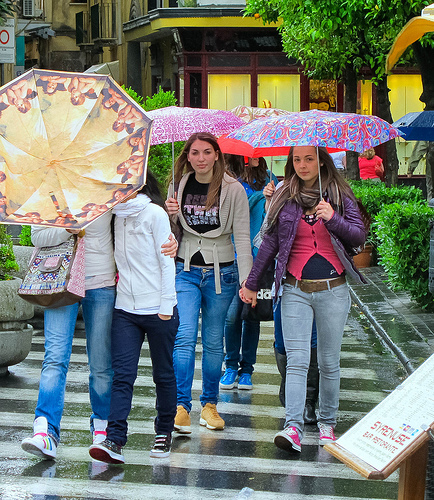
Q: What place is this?
A: It is a sidewalk.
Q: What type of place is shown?
A: It is a sidewalk.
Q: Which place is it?
A: It is a sidewalk.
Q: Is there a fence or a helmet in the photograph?
A: No, there are no fences or helmets.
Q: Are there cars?
A: No, there are no cars.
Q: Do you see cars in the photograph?
A: No, there are no cars.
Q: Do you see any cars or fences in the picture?
A: No, there are no cars or fences.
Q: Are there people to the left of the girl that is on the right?
A: Yes, there is a person to the left of the girl.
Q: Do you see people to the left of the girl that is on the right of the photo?
A: Yes, there is a person to the left of the girl.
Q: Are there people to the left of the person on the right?
A: Yes, there is a person to the left of the girl.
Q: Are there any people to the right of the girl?
A: No, the person is to the left of the girl.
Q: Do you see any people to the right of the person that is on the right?
A: No, the person is to the left of the girl.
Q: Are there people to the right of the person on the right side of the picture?
A: No, the person is to the left of the girl.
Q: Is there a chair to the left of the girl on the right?
A: No, there is a person to the left of the girl.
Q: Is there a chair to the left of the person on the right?
A: No, there is a person to the left of the girl.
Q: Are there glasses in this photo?
A: No, there are no glasses.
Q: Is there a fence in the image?
A: No, there are no fences.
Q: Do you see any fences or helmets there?
A: No, there are no fences or helmets.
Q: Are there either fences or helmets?
A: No, there are no fences or helmets.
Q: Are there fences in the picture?
A: No, there are no fences.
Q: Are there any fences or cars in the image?
A: No, there are no fences or cars.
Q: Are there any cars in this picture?
A: No, there are no cars.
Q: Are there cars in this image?
A: No, there are no cars.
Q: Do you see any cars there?
A: No, there are no cars.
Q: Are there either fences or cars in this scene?
A: No, there are no cars or fences.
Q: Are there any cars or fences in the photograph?
A: No, there are no cars or fences.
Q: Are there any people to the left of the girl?
A: Yes, there is a person to the left of the girl.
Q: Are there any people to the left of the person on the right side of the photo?
A: Yes, there is a person to the left of the girl.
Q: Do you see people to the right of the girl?
A: No, the person is to the left of the girl.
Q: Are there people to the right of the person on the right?
A: No, the person is to the left of the girl.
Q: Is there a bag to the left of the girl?
A: No, there is a person to the left of the girl.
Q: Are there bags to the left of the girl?
A: No, there is a person to the left of the girl.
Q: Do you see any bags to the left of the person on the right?
A: No, there is a person to the left of the girl.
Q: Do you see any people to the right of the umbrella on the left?
A: Yes, there is a person to the right of the umbrella.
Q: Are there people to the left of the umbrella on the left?
A: No, the person is to the right of the umbrella.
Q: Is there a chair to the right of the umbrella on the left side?
A: No, there is a person to the right of the umbrella.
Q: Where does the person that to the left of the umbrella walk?
A: The person walks on the sidewalk.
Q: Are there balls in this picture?
A: No, there are no balls.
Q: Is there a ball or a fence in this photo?
A: No, there are no balls or fences.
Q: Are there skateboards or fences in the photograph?
A: No, there are no fences or skateboards.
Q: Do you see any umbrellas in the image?
A: Yes, there is an umbrella.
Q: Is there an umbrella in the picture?
A: Yes, there is an umbrella.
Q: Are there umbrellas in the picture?
A: Yes, there is an umbrella.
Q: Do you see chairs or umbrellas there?
A: Yes, there is an umbrella.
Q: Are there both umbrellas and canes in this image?
A: No, there is an umbrella but no canes.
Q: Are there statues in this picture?
A: No, there are no statues.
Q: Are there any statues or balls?
A: No, there are no statues or balls.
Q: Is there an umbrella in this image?
A: Yes, there is an umbrella.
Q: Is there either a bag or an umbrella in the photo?
A: Yes, there is an umbrella.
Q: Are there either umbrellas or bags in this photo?
A: Yes, there is an umbrella.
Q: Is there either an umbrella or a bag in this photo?
A: Yes, there is an umbrella.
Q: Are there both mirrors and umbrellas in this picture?
A: No, there is an umbrella but no mirrors.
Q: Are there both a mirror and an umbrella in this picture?
A: No, there is an umbrella but no mirrors.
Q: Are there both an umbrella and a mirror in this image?
A: No, there is an umbrella but no mirrors.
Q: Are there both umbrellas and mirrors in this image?
A: No, there is an umbrella but no mirrors.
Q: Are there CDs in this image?
A: No, there are no cds.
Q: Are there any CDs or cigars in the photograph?
A: No, there are no CDs or cigars.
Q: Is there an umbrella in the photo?
A: Yes, there is an umbrella.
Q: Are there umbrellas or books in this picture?
A: Yes, there is an umbrella.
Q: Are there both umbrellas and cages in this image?
A: No, there is an umbrella but no cages.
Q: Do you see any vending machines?
A: No, there are no vending machines.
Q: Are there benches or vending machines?
A: No, there are no vending machines or benches.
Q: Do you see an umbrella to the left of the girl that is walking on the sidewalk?
A: Yes, there is an umbrella to the left of the girl.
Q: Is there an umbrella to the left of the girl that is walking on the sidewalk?
A: Yes, there is an umbrella to the left of the girl.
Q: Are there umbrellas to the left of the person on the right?
A: Yes, there is an umbrella to the left of the girl.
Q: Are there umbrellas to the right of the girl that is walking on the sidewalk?
A: No, the umbrella is to the left of the girl.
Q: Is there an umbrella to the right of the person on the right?
A: No, the umbrella is to the left of the girl.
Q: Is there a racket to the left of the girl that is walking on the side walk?
A: No, there is an umbrella to the left of the girl.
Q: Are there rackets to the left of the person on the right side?
A: No, there is an umbrella to the left of the girl.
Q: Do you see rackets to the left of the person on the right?
A: No, there is an umbrella to the left of the girl.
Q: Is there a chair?
A: No, there are no chairs.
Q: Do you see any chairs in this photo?
A: No, there are no chairs.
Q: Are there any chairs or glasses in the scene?
A: No, there are no chairs or glasses.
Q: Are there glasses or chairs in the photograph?
A: No, there are no chairs or glasses.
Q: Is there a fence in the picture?
A: No, there are no fences.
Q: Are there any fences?
A: No, there are no fences.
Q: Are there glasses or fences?
A: No, there are no fences or glasses.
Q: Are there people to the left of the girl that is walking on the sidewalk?
A: Yes, there is a person to the left of the girl.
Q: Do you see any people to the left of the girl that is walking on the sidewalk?
A: Yes, there is a person to the left of the girl.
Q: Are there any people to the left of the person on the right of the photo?
A: Yes, there is a person to the left of the girl.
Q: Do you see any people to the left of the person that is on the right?
A: Yes, there is a person to the left of the girl.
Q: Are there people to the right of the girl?
A: No, the person is to the left of the girl.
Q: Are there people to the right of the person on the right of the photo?
A: No, the person is to the left of the girl.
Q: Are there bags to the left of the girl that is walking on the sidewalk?
A: No, there is a person to the left of the girl.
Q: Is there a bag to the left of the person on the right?
A: No, there is a person to the left of the girl.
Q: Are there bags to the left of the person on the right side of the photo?
A: No, there is a person to the left of the girl.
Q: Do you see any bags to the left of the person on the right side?
A: No, there is a person to the left of the girl.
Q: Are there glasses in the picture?
A: No, there are no glasses.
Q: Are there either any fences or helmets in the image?
A: No, there are no fences or helmets.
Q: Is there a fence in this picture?
A: No, there are no fences.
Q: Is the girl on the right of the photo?
A: Yes, the girl is on the right of the image.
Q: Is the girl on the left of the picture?
A: No, the girl is on the right of the image.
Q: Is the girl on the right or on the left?
A: The girl is on the right of the image.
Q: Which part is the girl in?
A: The girl is on the right of the image.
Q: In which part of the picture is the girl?
A: The girl is on the right of the image.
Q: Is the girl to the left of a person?
A: No, the girl is to the right of a person.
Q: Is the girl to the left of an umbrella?
A: No, the girl is to the right of an umbrella.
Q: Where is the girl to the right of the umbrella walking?
A: The girl is walking on the sidewalk.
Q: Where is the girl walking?
A: The girl is walking on the sidewalk.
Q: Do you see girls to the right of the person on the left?
A: Yes, there is a girl to the right of the person.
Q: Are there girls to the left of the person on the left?
A: No, the girl is to the right of the person.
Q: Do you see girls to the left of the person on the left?
A: No, the girl is to the right of the person.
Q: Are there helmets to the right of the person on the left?
A: No, there is a girl to the right of the person.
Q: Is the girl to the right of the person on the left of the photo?
A: Yes, the girl is to the right of the person.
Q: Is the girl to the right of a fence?
A: No, the girl is to the right of the person.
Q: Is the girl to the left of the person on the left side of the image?
A: No, the girl is to the right of the person.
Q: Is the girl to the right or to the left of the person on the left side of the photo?
A: The girl is to the right of the person.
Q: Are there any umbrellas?
A: Yes, there is an umbrella.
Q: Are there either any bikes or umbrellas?
A: Yes, there is an umbrella.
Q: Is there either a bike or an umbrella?
A: Yes, there is an umbrella.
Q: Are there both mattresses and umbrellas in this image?
A: No, there is an umbrella but no mattresses.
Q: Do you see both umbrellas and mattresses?
A: No, there is an umbrella but no mattresses.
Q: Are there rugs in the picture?
A: No, there are no rugs.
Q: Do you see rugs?
A: No, there are no rugs.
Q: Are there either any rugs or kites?
A: No, there are no rugs or kites.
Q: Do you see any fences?
A: No, there are no fences.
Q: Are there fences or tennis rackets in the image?
A: No, there are no fences or tennis rackets.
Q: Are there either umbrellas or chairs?
A: Yes, there is an umbrella.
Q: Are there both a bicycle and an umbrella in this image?
A: No, there is an umbrella but no bicycles.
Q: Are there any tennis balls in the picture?
A: No, there are no tennis balls.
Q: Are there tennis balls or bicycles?
A: No, there are no tennis balls or bicycles.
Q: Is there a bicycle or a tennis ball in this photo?
A: No, there are no tennis balls or bicycles.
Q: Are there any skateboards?
A: No, there are no skateboards.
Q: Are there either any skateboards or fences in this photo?
A: No, there are no skateboards or fences.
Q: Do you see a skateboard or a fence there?
A: No, there are no skateboards or fences.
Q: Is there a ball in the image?
A: No, there are no balls.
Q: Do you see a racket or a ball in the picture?
A: No, there are no balls or rackets.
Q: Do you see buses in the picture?
A: No, there are no buses.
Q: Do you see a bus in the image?
A: No, there are no buses.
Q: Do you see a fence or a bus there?
A: No, there are no buses or fences.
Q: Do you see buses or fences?
A: No, there are no buses or fences.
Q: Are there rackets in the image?
A: No, there are no rackets.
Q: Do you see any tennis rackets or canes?
A: No, there are no tennis rackets or canes.